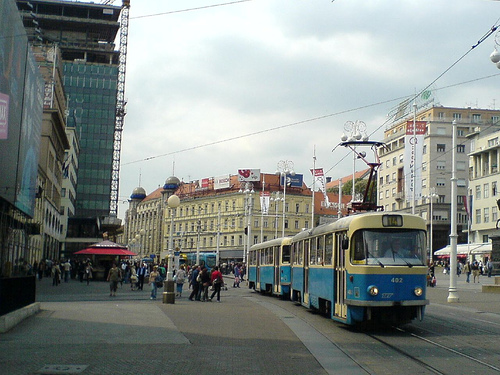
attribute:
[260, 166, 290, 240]
pole — white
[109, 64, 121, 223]
tower — tall, metal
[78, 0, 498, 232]
clouds — white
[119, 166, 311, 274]
building — multi story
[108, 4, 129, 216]
scaffold — metal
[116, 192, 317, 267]
building — yellow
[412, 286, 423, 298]
headlight — the left, in front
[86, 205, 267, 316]
people — crowd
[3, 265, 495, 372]
street — gray, asphalt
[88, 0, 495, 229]
skies — blue, cloudy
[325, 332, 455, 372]
tracks — train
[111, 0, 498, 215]
sky — turbulent , white and blue, overcast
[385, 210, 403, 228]
fourteen — number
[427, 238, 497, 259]
awning — white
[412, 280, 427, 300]
headlight — in front, the right